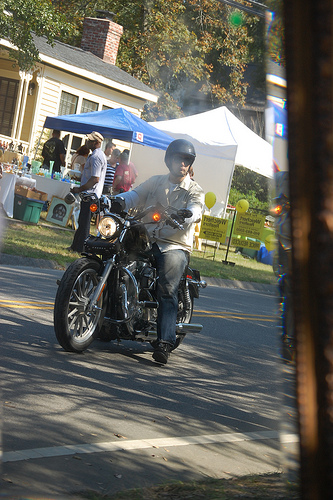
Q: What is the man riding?
A: Motorcycle.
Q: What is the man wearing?
A: Helmet.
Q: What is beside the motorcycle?
A: House.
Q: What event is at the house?
A: Yard house.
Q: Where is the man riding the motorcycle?
A: Street.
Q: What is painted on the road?
A: Yellow lines.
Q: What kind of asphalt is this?
A: This is black asphalt.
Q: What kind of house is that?
A: A yellow house.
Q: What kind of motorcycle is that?
A: A Harley.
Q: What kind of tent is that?
A: A white tent.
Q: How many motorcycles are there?
A: One.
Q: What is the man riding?
A: A motorcycle.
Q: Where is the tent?
A: In the yard.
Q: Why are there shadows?
A: It is sunny.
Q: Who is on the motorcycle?
A: The man.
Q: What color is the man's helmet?
A: Black.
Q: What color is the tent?
A: Blue.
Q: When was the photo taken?
A: Daytime.